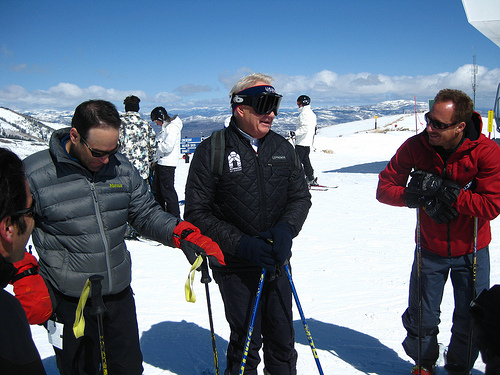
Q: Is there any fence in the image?
A: No, there are no fences.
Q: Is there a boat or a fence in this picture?
A: No, there are no fences or boats.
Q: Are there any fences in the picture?
A: No, there are no fences.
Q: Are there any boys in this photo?
A: No, there are no boys.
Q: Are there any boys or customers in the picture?
A: No, there are no boys or customers.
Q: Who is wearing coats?
A: The man is wearing coats.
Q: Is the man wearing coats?
A: Yes, the man is wearing coats.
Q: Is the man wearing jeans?
A: No, the man is wearing coats.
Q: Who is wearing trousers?
A: The man is wearing trousers.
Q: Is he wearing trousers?
A: Yes, the man is wearing trousers.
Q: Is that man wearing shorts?
A: No, the man is wearing trousers.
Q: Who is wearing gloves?
A: The man is wearing gloves.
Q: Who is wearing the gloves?
A: The man is wearing gloves.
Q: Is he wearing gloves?
A: Yes, the man is wearing gloves.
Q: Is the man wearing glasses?
A: No, the man is wearing gloves.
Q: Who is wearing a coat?
A: The man is wearing a coat.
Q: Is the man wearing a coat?
A: Yes, the man is wearing a coat.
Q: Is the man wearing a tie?
A: No, the man is wearing a coat.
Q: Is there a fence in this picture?
A: No, there are no fences.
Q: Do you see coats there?
A: Yes, there is a coat.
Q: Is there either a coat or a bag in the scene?
A: Yes, there is a coat.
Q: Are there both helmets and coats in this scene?
A: Yes, there are both a coat and a helmet.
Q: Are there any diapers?
A: No, there are no diapers.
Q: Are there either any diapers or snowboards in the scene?
A: No, there are no diapers or snowboards.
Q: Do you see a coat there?
A: Yes, there is a coat.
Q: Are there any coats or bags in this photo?
A: Yes, there is a coat.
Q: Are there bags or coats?
A: Yes, there is a coat.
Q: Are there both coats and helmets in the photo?
A: Yes, there are both a coat and a helmet.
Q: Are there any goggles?
A: Yes, there are goggles.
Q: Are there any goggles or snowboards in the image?
A: Yes, there are goggles.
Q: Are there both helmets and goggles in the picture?
A: Yes, there are both goggles and a helmet.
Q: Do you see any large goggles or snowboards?
A: Yes, there are large goggles.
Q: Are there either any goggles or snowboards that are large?
A: Yes, the goggles are large.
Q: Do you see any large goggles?
A: Yes, there are large goggles.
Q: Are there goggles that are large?
A: Yes, there are goggles that are large.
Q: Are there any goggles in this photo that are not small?
A: Yes, there are large goggles.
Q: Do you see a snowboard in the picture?
A: No, there are no snowboards.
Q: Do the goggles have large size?
A: Yes, the goggles are large.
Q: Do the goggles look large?
A: Yes, the goggles are large.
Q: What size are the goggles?
A: The goggles are large.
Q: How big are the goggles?
A: The goggles are large.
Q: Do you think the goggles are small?
A: No, the goggles are large.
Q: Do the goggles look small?
A: No, the goggles are large.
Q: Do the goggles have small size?
A: No, the goggles are large.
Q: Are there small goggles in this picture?
A: No, there are goggles but they are large.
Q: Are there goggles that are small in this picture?
A: No, there are goggles but they are large.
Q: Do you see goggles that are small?
A: No, there are goggles but they are large.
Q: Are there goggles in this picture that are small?
A: No, there are goggles but they are large.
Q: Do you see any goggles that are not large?
A: No, there are goggles but they are large.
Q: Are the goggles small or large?
A: The goggles are large.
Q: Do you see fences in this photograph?
A: No, there are no fences.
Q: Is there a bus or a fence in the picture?
A: No, there are no fences or buses.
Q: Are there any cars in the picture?
A: No, there are no cars.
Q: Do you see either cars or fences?
A: No, there are no cars or fences.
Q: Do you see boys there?
A: No, there are no boys.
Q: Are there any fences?
A: No, there are no fences.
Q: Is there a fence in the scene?
A: No, there are no fences.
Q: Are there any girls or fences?
A: No, there are no fences or girls.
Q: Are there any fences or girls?
A: No, there are no fences or girls.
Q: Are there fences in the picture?
A: No, there are no fences.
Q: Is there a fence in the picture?
A: No, there are no fences.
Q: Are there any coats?
A: Yes, there is a coat.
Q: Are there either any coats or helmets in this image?
A: Yes, there is a coat.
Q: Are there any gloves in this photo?
A: Yes, there are gloves.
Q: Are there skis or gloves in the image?
A: Yes, there are gloves.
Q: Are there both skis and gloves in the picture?
A: Yes, there are both gloves and a ski.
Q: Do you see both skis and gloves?
A: Yes, there are both gloves and a ski.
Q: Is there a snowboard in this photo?
A: No, there are no snowboards.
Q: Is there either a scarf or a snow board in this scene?
A: No, there are no snowboards or scarves.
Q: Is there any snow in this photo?
A: Yes, there is snow.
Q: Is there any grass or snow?
A: Yes, there is snow.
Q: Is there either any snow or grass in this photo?
A: Yes, there is snow.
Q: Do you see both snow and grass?
A: No, there is snow but no grass.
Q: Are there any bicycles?
A: No, there are no bicycles.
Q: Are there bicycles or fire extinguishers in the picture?
A: No, there are no bicycles or fire extinguishers.